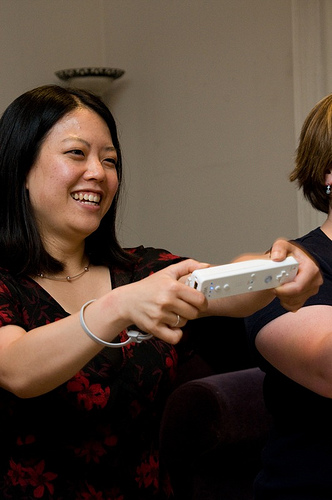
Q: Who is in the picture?
A: A woman.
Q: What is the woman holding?
A: A wii.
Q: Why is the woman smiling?
A: She is playing a game.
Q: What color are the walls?
A: Cream.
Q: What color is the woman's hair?
A: Black.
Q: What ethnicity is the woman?
A: Asian.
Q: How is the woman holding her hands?
A: Out in front of her.